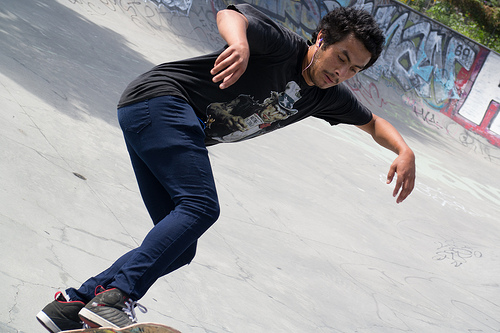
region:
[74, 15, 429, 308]
man on skate board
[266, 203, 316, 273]
light gray skate park pavement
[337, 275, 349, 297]
light gray skate park pavement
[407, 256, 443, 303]
light gray skate park pavement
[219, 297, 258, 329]
light gray skate park pavement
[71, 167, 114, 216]
light gray skate park pavement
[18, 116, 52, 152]
light gray skate park pavement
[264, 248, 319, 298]
light gray skate park pavement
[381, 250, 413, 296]
light gray skate park pavement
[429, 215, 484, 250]
light gray skate park pavement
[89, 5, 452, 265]
man riding a skateboard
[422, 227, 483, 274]
writing on pavement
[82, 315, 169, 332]
skateboard on the ground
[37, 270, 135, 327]
feet on the skateboard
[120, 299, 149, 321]
laces on a shoe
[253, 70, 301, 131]
uncle sam on a shirt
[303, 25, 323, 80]
earbud in man's ear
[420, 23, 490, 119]
grafiti on the wall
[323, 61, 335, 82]
mustache on man's face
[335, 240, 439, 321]
lines in the pavement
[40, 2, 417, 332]
Man on a skateboard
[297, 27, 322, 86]
Earbuds in a man's ear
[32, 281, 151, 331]
Black skater shoes with white soles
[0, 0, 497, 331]
Large cement skate park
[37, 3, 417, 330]
Man riding up a skate ramp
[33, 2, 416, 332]
Man wearing a black shirt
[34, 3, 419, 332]
Man wearing blue skinny jeans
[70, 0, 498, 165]
Graffiti on a skate park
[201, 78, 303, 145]
Print of Uncle Sam on a shirt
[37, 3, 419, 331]
Man looking scared on a skateboard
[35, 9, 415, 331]
man skateboarding on ramp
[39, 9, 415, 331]
skateboarder with curly hair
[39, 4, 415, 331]
skateboarder with black hair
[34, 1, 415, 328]
skateboarder with black t-shirt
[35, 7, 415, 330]
skateboarder with blue jeans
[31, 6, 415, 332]
person on skateboard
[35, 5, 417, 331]
person wearing black sneakers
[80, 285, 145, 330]
black sneaker with white shoelace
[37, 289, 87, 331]
black sneaker with white sole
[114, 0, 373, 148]
uncle sam on black t-shirt